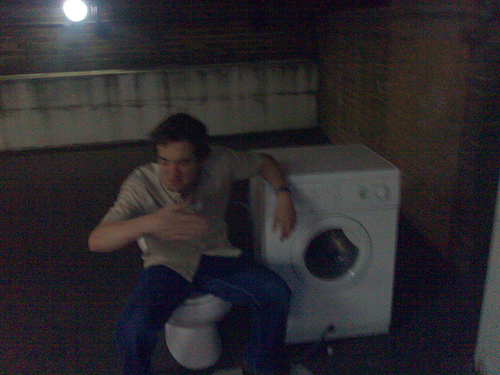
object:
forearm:
[258, 152, 292, 202]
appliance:
[246, 142, 405, 346]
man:
[87, 110, 299, 375]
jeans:
[112, 251, 293, 375]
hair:
[147, 112, 213, 162]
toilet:
[162, 286, 234, 372]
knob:
[373, 182, 390, 202]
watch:
[273, 186, 291, 196]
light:
[58, 0, 92, 24]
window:
[304, 228, 359, 282]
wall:
[0, 57, 322, 154]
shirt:
[99, 145, 266, 284]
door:
[289, 216, 372, 294]